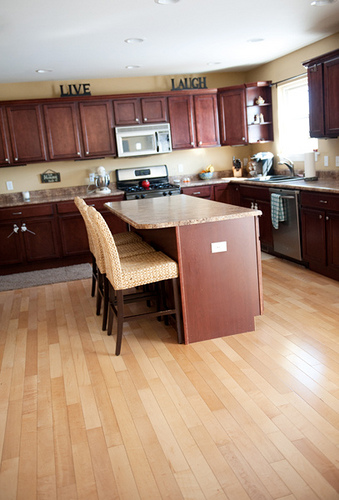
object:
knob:
[77, 152, 80, 156]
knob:
[136, 118, 139, 122]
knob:
[319, 215, 322, 219]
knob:
[326, 216, 329, 220]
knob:
[199, 141, 202, 146]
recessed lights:
[123, 36, 145, 70]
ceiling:
[0, 0, 339, 85]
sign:
[40, 169, 61, 183]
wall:
[0, 47, 339, 195]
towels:
[304, 150, 317, 179]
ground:
[0, 242, 339, 499]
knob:
[15, 158, 19, 163]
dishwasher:
[271, 190, 302, 264]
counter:
[222, 175, 338, 193]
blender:
[94, 166, 111, 195]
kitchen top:
[0, 184, 125, 207]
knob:
[86, 151, 90, 155]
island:
[107, 195, 266, 348]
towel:
[270, 192, 287, 230]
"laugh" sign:
[170, 76, 208, 91]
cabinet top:
[130, 80, 272, 92]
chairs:
[73, 195, 183, 357]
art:
[59, 82, 91, 96]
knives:
[232, 154, 242, 175]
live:
[59, 82, 91, 97]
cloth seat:
[270, 192, 288, 230]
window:
[276, 75, 320, 158]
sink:
[244, 174, 303, 184]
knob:
[191, 142, 194, 145]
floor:
[0, 251, 339, 498]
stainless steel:
[232, 150, 305, 183]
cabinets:
[0, 75, 272, 178]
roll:
[303, 152, 317, 179]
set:
[232, 155, 241, 172]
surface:
[0, 254, 339, 499]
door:
[42, 102, 83, 161]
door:
[111, 95, 142, 126]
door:
[193, 91, 220, 148]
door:
[299, 193, 326, 278]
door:
[324, 203, 339, 284]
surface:
[104, 193, 262, 232]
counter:
[101, 194, 262, 231]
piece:
[59, 83, 91, 98]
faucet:
[277, 153, 295, 178]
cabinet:
[297, 190, 339, 281]